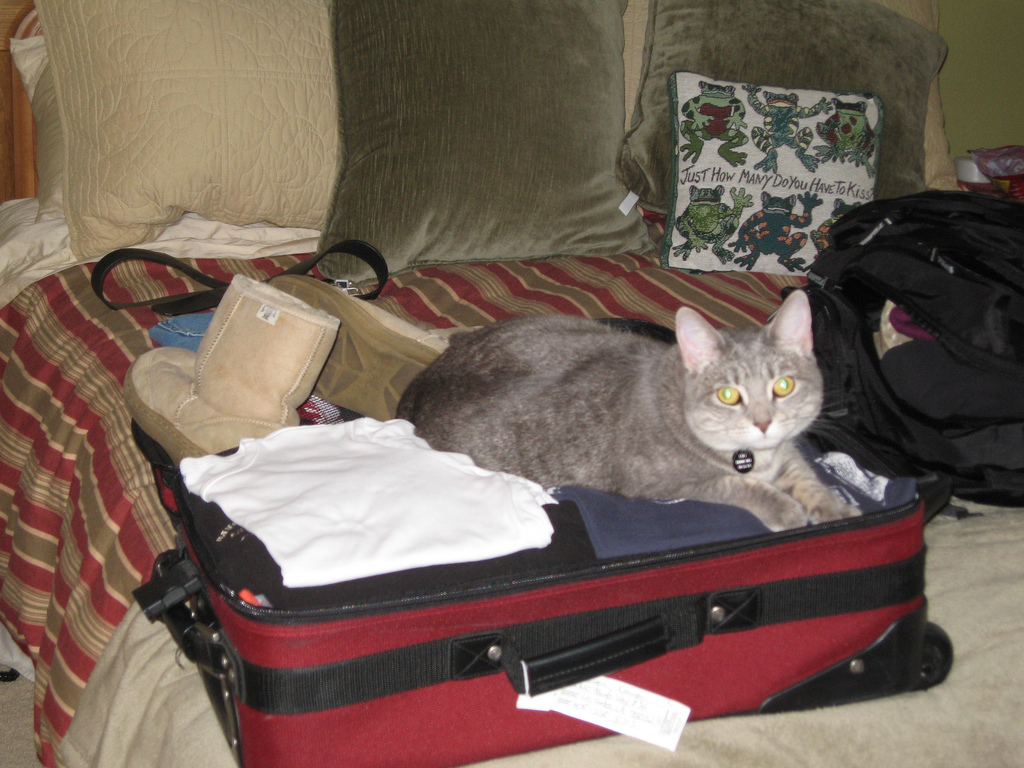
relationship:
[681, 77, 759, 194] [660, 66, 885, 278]
frog on pillow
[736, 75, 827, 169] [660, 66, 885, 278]
frog on pillow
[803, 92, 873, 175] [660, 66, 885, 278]
frog on pillow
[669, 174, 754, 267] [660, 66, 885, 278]
frog on pillow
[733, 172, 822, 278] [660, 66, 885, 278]
frog on pillow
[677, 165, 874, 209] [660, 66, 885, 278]
lettering on pillow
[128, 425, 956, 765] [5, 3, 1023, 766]
suitcase on bed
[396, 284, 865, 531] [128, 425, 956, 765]
cat laying on top of suitcase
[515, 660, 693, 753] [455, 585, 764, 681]
tag on handle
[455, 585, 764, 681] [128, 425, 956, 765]
handle on suitcase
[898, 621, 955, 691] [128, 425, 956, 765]
wheel on suitcase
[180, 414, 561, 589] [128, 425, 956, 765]
shirt packed in suitcase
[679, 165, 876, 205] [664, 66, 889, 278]
lettering on throw pillow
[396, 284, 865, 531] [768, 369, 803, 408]
cat has eye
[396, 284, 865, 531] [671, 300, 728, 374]
cat has ear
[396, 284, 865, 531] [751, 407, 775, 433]
cat has nose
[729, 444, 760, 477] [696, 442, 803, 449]
tag on collar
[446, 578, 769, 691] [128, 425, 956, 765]
handle on suitcase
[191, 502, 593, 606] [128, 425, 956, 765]
shirt in suitcase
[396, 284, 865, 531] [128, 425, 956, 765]
cat sitting in suitcase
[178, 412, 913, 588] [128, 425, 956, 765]
clothes in suitcase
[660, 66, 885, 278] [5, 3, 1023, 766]
pillow on bed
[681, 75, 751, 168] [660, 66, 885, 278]
frog on pillow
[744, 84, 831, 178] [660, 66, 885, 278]
frog on pillow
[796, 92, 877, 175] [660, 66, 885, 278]
frog on pillow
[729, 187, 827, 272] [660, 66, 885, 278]
frog on pillow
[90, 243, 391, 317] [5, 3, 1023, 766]
belt on bed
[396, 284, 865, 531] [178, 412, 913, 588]
cat laying on clothes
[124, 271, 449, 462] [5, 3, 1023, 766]
boots on bed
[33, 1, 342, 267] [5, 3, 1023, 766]
pillow on bed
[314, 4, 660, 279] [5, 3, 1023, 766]
pillow on bed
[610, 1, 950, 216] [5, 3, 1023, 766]
pillow on bed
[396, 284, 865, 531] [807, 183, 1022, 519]
cat laying by duffel bag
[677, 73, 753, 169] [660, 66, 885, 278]
frog on pillow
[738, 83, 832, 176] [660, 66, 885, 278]
frog on pillow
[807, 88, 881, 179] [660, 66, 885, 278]
frog on pillow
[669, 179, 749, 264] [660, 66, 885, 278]
frog on pillow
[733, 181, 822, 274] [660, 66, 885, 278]
frog on pillow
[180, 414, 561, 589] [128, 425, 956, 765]
shirt in suitcase